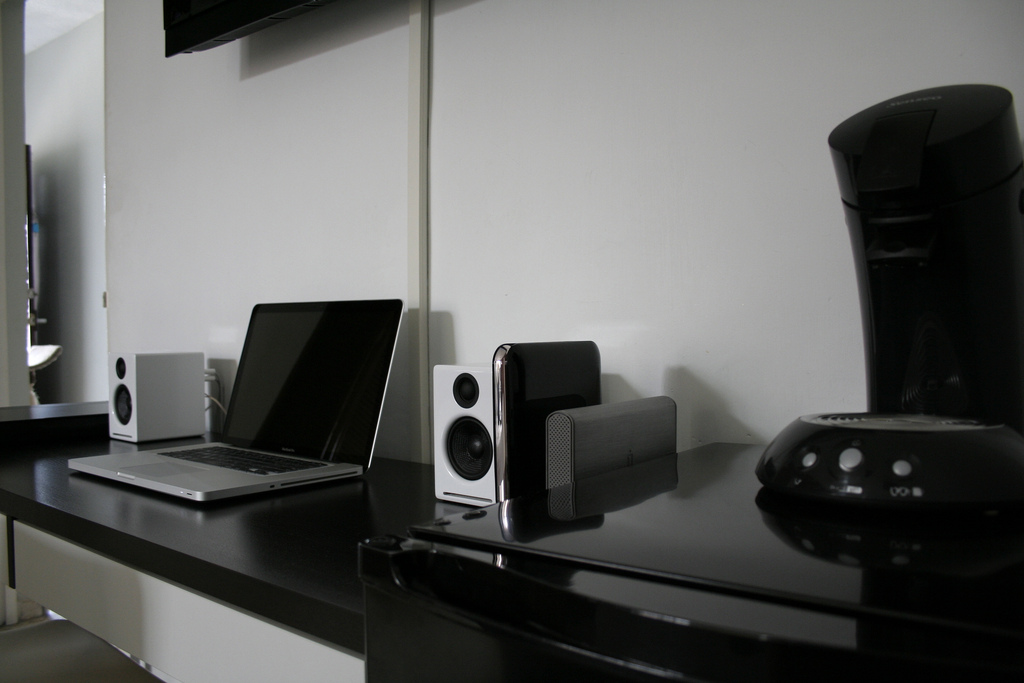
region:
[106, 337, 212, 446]
a white speaker on the counter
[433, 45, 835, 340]
the wall is mainly white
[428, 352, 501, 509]
white computer speaker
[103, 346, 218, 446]
white computer speaker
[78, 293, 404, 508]
open silver thin Mac laptop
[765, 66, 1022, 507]
black plastic coffee maker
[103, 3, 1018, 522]
clean white wall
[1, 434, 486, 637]
very clean black smooth counter top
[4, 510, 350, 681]
clean white long drawer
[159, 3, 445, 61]
bottom left corner of a flatscreen tv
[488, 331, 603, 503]
thin black and silver modem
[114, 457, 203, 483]
mouse track pad on mac laptop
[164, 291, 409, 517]
Laptop computer stationed open.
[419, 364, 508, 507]
Computer speakers for the laptop.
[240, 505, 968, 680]
Small black mini fridge.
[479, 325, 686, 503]
Wireless router and regular router for internet.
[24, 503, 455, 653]
A small black desk for a laptop.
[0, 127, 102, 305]
Hallway in the house.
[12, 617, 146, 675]
Carpeting on the floor.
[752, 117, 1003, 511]
A coffee maker of some type.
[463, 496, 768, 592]
The light shining a reflection.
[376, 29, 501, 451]
White housing for hiding cables.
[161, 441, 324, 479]
black keyboard of a laptop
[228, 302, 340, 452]
reflection of laptop's monitor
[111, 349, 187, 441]
black and white speaker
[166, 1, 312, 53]
black object hanging on wall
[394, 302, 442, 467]
shadow of laptop on wall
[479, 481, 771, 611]
objects reflected on black shiny surface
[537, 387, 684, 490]
grey book-like object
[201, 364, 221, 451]
electrical cords behind speaker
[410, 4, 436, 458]
white covering for electrical cord on wall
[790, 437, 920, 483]
grey buttons on a small black device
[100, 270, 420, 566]
nice workstation with laptop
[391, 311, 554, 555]
speakers for computer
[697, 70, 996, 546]
fan for work area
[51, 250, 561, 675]
neat and clean workstation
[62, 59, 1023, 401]
freshly painted offices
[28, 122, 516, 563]
ready for a busy day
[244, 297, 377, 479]
laptop is turned off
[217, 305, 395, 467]
The screen is black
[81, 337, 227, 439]
speaker's body is white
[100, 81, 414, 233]
the wall is white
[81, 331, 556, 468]
two speakers in both sides of laptop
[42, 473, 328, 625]
the desktop is black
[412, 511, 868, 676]
the fridge is black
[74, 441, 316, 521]
the key board is black and silver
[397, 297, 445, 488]
shadow of laptop screen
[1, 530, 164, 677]
the desk is black and white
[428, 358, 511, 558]
Speaker shows top, circle smaller than bottom one.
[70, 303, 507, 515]
White-cased speakers, identical.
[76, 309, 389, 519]
Open laptop, with screen off.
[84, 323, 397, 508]
Casing silver, keys black.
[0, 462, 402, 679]
Desktop black, side white.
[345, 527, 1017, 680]
Looks like black file cabinet, open.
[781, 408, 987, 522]
Three silver buttons on black apperatus.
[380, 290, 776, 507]
Shadows of items on desk.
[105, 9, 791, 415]
White wall with frame corner.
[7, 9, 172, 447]
Opening to another white room.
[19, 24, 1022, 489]
Black and white photo.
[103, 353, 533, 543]
Pair of white speakers.